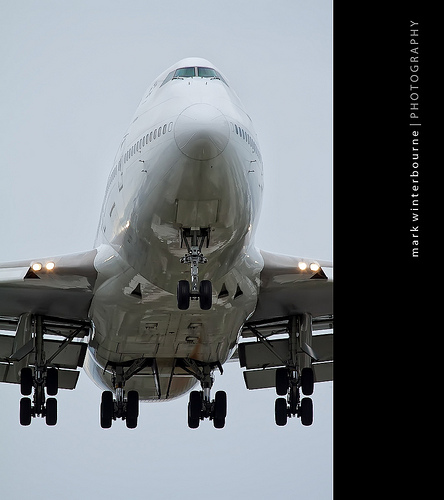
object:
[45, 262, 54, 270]
lights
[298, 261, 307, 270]
lights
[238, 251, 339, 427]
airplane wing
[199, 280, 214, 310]
wheels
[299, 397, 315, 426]
wheels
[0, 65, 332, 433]
plane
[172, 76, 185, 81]
wiper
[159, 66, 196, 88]
window